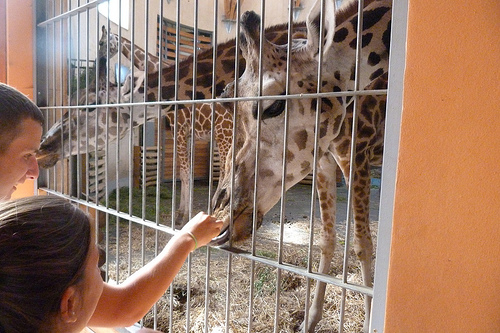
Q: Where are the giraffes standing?
A: Hay.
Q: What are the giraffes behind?
A: Bars.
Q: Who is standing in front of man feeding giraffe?
A: Girl with brown hair.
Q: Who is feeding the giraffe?
A: Man with bracelet.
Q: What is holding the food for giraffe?
A: Hand.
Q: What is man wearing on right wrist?
A: Bracelet.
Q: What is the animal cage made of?
A: Metal.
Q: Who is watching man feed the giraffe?
A: Girl with brown hair.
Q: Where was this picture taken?
A: Zoo.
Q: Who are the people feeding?
A: Giraffes.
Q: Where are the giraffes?
A: In Enclosure.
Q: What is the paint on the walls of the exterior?
A: Orange.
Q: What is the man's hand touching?
A: Metal cage.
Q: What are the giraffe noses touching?
A: Metal cage.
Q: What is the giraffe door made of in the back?
A: Wood.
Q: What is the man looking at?
A: Giraffes mouth.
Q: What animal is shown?
A: Giraffe.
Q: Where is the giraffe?
A: In the cage.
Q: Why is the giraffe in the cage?
A: For a zoo.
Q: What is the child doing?
A: Feeding the giraffe.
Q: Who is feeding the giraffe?
A: The child.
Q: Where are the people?
A: Outside the cage.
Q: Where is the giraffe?
A: In a zoo.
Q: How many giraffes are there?
A: Three.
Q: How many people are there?
A: Two.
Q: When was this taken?
A: During the day.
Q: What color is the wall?
A: Orange.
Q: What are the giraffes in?
A: A cage.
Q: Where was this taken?
A: At a zoo.